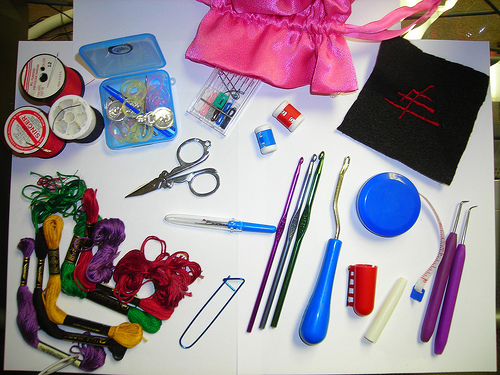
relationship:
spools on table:
[3, 50, 103, 162] [20, 5, 498, 373]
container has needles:
[29, 31, 478, 372] [243, 150, 326, 342]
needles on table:
[238, 135, 358, 365] [137, 81, 456, 364]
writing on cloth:
[375, 79, 448, 130] [335, 44, 497, 180]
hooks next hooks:
[255, 139, 301, 335] [304, 150, 328, 299]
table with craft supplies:
[21, 32, 496, 317] [17, 47, 490, 362]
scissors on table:
[127, 139, 222, 204] [459, 3, 498, 43]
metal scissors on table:
[115, 136, 222, 204] [21, 47, 483, 373]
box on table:
[77, 33, 176, 150] [20, 5, 498, 373]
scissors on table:
[127, 139, 222, 204] [79, 149, 456, 362]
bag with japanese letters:
[336, 37, 491, 190] [385, 77, 450, 127]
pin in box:
[217, 67, 242, 102] [183, 65, 264, 138]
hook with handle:
[299, 154, 351, 346] [299, 238, 341, 344]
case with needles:
[174, 55, 277, 144] [199, 97, 238, 130]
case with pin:
[174, 55, 277, 144] [211, 67, 242, 99]